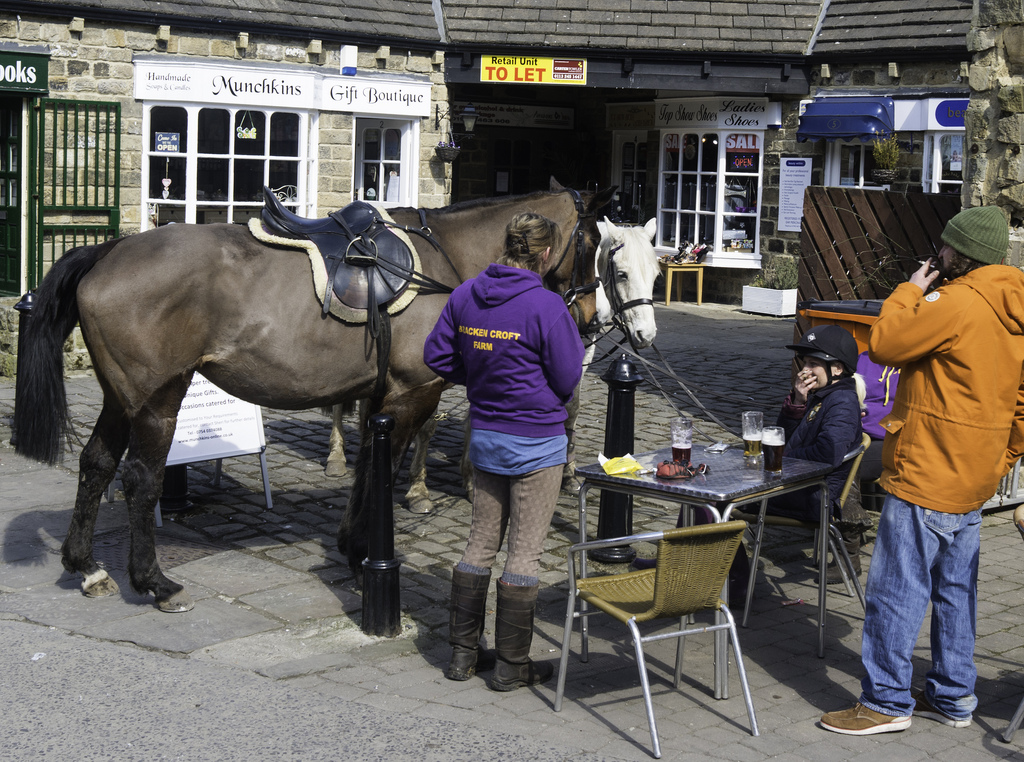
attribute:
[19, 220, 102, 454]
tail — black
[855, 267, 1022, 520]
jacket — orange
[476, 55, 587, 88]
sign — yellow, red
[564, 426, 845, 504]
table — square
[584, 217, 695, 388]
head — white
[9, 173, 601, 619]
horse — brown, large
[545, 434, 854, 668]
table — square, metal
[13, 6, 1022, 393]
building — brick, stone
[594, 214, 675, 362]
horse — white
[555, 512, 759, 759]
chair — brown, small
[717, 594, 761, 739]
leg — metal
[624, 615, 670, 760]
leg — metal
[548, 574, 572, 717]
leg — metal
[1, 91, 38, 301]
door — green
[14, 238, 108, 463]
tail — black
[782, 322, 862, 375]
helmet — black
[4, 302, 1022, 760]
square — cobbled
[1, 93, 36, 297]
gate — green, iron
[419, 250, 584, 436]
sweatshirt — purple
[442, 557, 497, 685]
boot — brown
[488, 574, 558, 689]
boot — brown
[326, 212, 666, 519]
horse — white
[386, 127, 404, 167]
glass — clean, clear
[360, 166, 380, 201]
glass — clear, clean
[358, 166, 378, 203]
glass — clean, clear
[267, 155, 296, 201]
glass — clear, clean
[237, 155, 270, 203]
glass — clean, clear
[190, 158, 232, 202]
glass — clear, clean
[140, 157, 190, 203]
glass — clean, clear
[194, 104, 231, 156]
glass — clean and clear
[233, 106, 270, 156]
glass — clean and clear